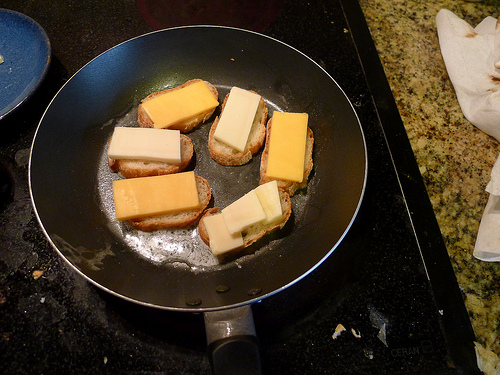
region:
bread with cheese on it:
[106, 171, 211, 226]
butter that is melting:
[131, 235, 201, 267]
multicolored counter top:
[356, 0, 498, 374]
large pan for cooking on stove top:
[26, 23, 369, 373]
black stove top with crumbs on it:
[1, 1, 476, 370]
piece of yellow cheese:
[266, 109, 306, 182]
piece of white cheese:
[108, 126, 182, 164]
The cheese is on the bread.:
[111, 169, 206, 223]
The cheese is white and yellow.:
[113, 166, 283, 251]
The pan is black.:
[24, 17, 380, 314]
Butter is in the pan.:
[126, 225, 219, 270]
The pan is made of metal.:
[26, 48, 387, 311]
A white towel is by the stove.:
[429, 2, 495, 265]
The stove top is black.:
[3, 2, 477, 374]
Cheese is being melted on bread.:
[128, 75, 218, 136]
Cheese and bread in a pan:
[101, 120, 189, 169]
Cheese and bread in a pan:
[96, 164, 212, 216]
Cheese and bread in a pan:
[187, 183, 291, 245]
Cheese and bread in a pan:
[261, 107, 313, 194]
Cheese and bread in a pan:
[208, 81, 268, 159]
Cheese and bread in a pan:
[140, 80, 210, 137]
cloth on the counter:
[421, 14, 499, 188]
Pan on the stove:
[23, 10, 380, 332]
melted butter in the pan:
[127, 225, 211, 277]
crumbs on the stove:
[313, 316, 380, 355]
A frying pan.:
[18, 24, 378, 371]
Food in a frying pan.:
[32, 20, 376, 370]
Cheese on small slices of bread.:
[105, 64, 329, 271]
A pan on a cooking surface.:
[9, 7, 475, 373]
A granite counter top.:
[366, 0, 498, 372]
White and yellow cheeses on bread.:
[98, 68, 328, 274]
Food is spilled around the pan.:
[5, 128, 458, 374]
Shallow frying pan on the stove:
[28, 23, 378, 373]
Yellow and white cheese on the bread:
[105, 74, 326, 256]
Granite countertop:
[354, 4, 498, 369]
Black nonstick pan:
[23, 20, 393, 330]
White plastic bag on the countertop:
[428, 5, 498, 250]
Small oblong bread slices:
[108, 72, 323, 259]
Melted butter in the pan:
[100, 213, 230, 278]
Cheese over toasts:
[104, 70, 318, 249]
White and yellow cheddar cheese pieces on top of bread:
[106, 79, 324, 266]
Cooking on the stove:
[16, 18, 379, 335]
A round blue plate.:
[0, 6, 50, 119]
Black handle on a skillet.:
[205, 338, 261, 375]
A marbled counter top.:
[359, 0, 499, 372]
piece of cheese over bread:
[267, 110, 304, 185]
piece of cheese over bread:
[201, 209, 251, 251]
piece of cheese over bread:
[247, 180, 288, 227]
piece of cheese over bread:
[109, 175, 199, 222]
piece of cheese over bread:
[100, 121, 185, 166]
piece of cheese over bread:
[213, 77, 264, 160]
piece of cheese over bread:
[266, 107, 312, 188]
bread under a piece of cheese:
[107, 170, 217, 225]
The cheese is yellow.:
[108, 175, 205, 228]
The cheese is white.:
[106, 123, 180, 165]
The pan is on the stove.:
[23, 21, 370, 312]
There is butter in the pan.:
[126, 232, 202, 269]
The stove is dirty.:
[1, 233, 83, 361]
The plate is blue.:
[2, 4, 54, 125]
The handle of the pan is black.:
[199, 311, 269, 371]